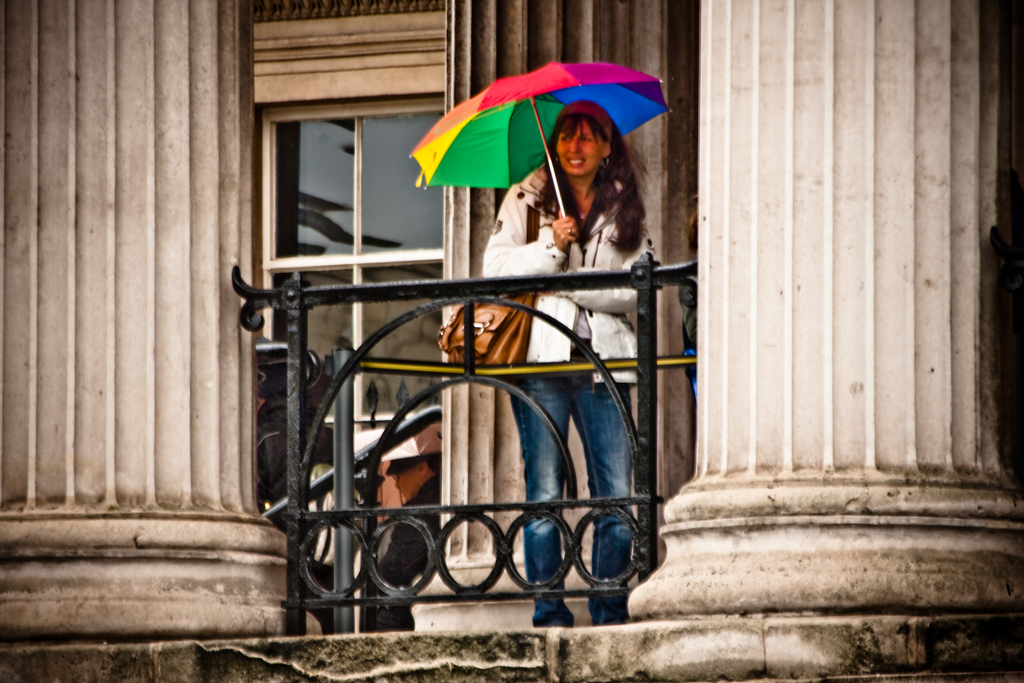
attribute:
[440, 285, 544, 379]
handbag — brown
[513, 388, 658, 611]
jeans — blue, faded, bright blue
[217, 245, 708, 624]
railing — black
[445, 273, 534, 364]
hand bag — camel brown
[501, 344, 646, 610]
jeans — blue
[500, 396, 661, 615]
jeans — blue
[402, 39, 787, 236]
umbrella — colorful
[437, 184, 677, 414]
jacket — white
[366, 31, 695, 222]
umbrella — rainbow colored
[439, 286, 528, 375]
purse — BROWN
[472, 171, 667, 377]
coat — WHITE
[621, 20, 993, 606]
pillar — WHITE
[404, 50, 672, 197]
umbrella — COLORFUL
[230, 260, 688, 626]
gate — BLACK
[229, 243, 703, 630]
fence — IRON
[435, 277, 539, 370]
bag — BROWN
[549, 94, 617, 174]
head — WOMAN'S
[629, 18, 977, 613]
coulmn — LARGE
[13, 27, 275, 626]
column — LARGE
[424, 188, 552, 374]
handbag — BROWN, OVER THE SHOULDER